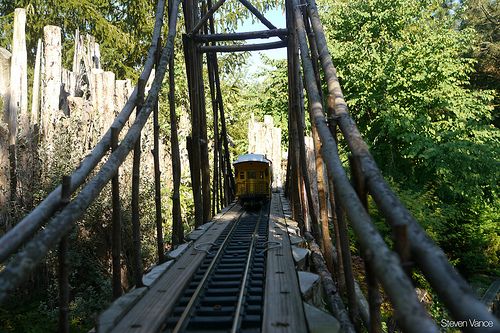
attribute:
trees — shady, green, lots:
[327, 25, 411, 74]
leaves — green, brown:
[76, 10, 106, 25]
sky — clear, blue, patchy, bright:
[266, 14, 275, 22]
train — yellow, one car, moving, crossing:
[229, 149, 273, 205]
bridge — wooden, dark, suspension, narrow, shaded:
[169, 232, 280, 282]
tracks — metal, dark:
[227, 214, 269, 238]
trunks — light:
[301, 204, 331, 233]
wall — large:
[80, 68, 132, 113]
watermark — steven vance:
[441, 316, 489, 328]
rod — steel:
[145, 6, 184, 24]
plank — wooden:
[271, 271, 310, 301]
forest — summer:
[245, 17, 371, 73]